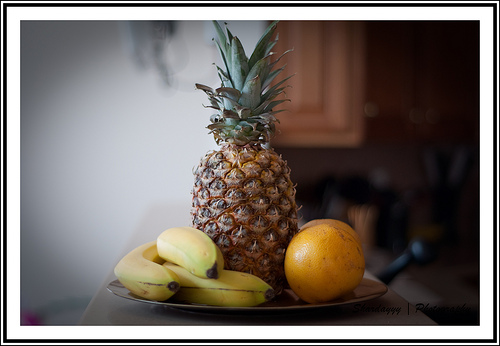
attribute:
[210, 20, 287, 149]
leaves — green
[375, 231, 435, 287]
appliance — black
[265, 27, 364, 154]
cabinet — kitchen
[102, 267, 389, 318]
plate — round, brown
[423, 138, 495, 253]
utensils — black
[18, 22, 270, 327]
wall — white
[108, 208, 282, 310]
banana — brown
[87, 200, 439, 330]
counter — white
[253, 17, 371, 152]
cabinet — open